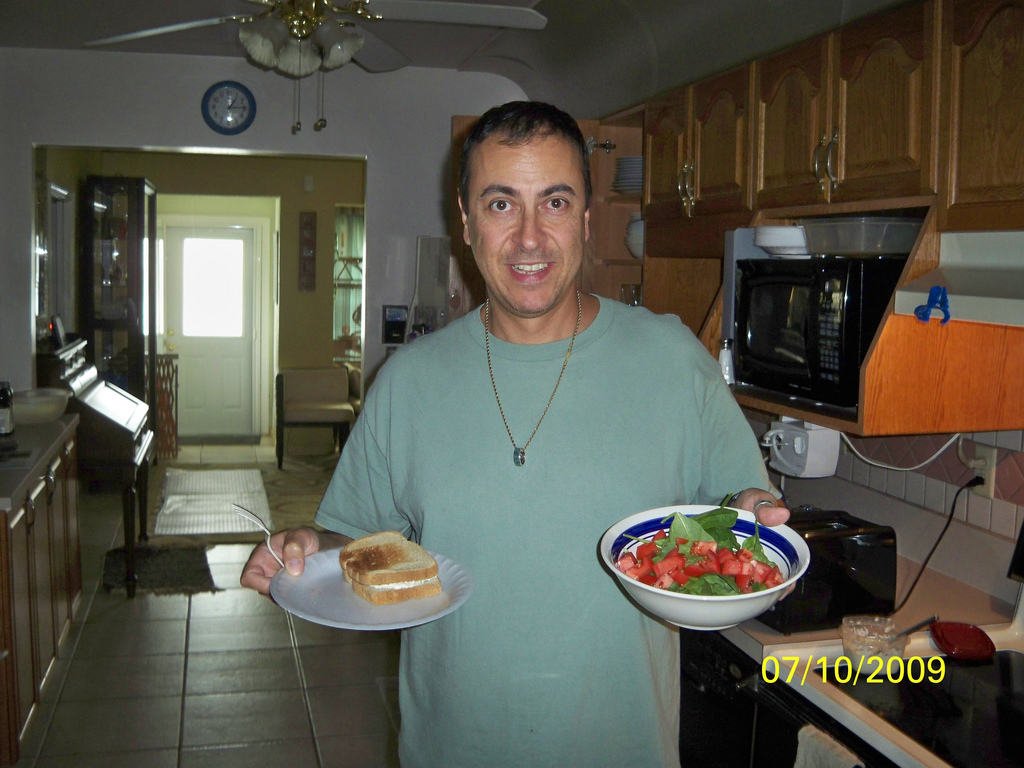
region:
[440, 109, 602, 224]
man has brown hair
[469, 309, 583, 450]
man is wearing necklace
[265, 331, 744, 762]
man has green shirt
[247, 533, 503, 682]
man holds paper plate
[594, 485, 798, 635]
man holds white bowl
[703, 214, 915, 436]
black microwave behind man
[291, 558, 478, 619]
sandwich on white plate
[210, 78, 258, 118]
blue and white clock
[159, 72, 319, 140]
white wall around clock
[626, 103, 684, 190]
a door for a cabinet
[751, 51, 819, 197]
a door for a cabinet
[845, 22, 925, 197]
a door for a cabinet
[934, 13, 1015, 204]
a door for a cabinet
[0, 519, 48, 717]
a door for a cabinet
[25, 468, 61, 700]
a door for a cabinet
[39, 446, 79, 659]
a door for a cabinet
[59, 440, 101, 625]
a door for a cabinet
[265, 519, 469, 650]
a plate made for dining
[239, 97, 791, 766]
man standing in home kitchen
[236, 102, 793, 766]
man wearing light green shirt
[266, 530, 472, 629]
styrofoam plate holding toasted sandwich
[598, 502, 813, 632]
blue and white bowl holding salad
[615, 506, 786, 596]
salad of greens and tomatoes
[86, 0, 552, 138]
ceiling fan hung from kitchen ceiling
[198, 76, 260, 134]
blue and white clock on wall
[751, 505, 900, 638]
black toaster on counter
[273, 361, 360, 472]
beige chair near front door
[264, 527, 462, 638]
a white plate with a sandwich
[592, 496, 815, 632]
a blue and white bowl of salad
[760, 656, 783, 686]
yellow print style number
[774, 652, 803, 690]
yellow print style number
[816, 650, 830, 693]
yellow print style number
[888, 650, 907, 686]
yellow print style number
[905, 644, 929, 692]
yellow print style number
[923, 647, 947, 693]
yellow print style number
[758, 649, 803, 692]
yellow print style numbers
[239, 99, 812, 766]
the man is standing in a kitchen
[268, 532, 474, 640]
the man is holding a white plate in one hand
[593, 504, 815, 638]
the bowl is white with a blue stripe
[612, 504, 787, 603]
there is a salad in the bowl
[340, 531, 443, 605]
there is a sandwich on the plate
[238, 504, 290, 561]
the man holds a utensil in the same hand as the plate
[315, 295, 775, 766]
the man is wearing a green t-shirt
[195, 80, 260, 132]
there is a clock over the doorway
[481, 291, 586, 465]
the man is wearing a necklace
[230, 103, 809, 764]
man holding white plate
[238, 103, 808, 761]
man holding white and blue bowl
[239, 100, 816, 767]
man is holding a white and blue bowl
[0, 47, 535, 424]
blue clock on the wall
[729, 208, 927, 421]
plastic container on top of black microwave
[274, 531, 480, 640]
sandwich on white paper plate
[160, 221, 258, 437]
window pane in white door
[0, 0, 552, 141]
white ceiling fan on the ceiling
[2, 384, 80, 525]
plastic bowl on the counter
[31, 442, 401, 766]
small brown rug on the tile floor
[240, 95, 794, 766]
man is wearing a light bluish green shirt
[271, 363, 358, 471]
wooden chair with beige cushions